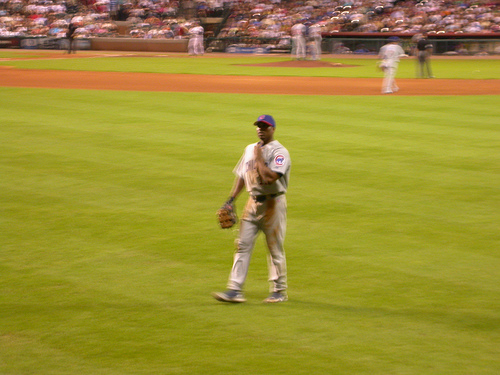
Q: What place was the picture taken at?
A: It was taken at the field.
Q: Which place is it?
A: It is a field.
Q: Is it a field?
A: Yes, it is a field.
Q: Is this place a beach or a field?
A: It is a field.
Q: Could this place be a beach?
A: No, it is a field.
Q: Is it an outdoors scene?
A: Yes, it is outdoors.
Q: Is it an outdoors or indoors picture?
A: It is outdoors.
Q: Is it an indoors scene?
A: No, it is outdoors.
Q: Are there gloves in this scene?
A: Yes, there are gloves.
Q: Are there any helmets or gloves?
A: Yes, there are gloves.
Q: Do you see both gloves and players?
A: Yes, there are both gloves and a player.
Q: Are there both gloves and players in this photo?
A: Yes, there are both gloves and a player.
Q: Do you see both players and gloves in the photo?
A: Yes, there are both gloves and a player.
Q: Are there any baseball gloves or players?
A: Yes, there are baseball gloves.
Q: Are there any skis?
A: No, there are no skis.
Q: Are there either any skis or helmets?
A: No, there are no skis or helmets.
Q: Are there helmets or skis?
A: No, there are no skis or helmets.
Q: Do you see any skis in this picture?
A: No, there are no skis.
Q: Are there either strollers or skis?
A: No, there are no skis or strollers.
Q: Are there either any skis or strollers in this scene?
A: No, there are no skis or strollers.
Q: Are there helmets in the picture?
A: No, there are no helmets.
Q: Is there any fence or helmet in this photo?
A: No, there are no helmets or fences.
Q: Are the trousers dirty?
A: Yes, the trousers are dirty.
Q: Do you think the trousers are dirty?
A: Yes, the trousers are dirty.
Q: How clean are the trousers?
A: The trousers are dirty.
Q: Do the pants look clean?
A: No, the pants are dirty.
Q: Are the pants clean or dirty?
A: The pants are dirty.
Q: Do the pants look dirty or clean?
A: The pants are dirty.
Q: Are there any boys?
A: No, there are no boys.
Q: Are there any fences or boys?
A: No, there are no boys or fences.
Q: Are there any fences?
A: No, there are no fences.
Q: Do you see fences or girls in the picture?
A: No, there are no fences or girls.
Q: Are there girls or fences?
A: No, there are no fences or girls.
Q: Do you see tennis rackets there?
A: No, there are no tennis rackets.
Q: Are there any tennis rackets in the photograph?
A: No, there are no tennis rackets.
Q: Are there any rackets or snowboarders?
A: No, there are no rackets or snowboarders.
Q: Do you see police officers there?
A: No, there are no police officers.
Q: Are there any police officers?
A: No, there are no police officers.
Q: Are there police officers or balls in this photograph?
A: No, there are no police officers or balls.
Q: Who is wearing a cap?
A: The player is wearing a cap.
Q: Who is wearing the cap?
A: The player is wearing a cap.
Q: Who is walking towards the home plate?
A: The player is walking towards the home plate.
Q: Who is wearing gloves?
A: The player is wearing gloves.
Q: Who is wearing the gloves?
A: The player is wearing gloves.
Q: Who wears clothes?
A: The player wears clothes.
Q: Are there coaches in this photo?
A: No, there are no coaches.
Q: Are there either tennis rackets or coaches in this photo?
A: No, there are no coaches or tennis rackets.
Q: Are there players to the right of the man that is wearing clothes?
A: Yes, there is a player to the right of the man.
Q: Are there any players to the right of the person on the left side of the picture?
A: Yes, there is a player to the right of the man.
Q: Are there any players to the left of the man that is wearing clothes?
A: No, the player is to the right of the man.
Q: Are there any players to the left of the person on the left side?
A: No, the player is to the right of the man.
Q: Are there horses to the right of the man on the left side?
A: No, there is a player to the right of the man.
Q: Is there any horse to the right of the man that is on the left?
A: No, there is a player to the right of the man.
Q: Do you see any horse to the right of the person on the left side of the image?
A: No, there is a player to the right of the man.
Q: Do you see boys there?
A: No, there are no boys.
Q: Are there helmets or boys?
A: No, there are no boys or helmets.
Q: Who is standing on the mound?
A: The player is standing on the mound.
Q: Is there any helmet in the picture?
A: No, there are no helmets.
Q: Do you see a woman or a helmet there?
A: No, there are no helmets or women.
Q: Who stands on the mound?
A: The player stands on the mound.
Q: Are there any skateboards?
A: No, there are no skateboards.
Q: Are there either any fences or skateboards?
A: No, there are no skateboards or fences.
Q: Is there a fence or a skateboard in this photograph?
A: No, there are no skateboards or fences.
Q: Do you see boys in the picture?
A: No, there are no boys.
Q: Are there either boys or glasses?
A: No, there are no boys or glasses.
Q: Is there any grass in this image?
A: Yes, there is grass.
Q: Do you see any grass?
A: Yes, there is grass.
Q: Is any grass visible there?
A: Yes, there is grass.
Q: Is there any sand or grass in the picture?
A: Yes, there is grass.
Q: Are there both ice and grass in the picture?
A: No, there is grass but no ice.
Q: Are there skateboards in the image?
A: No, there are no skateboards.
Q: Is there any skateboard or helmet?
A: No, there are no skateboards or helmets.